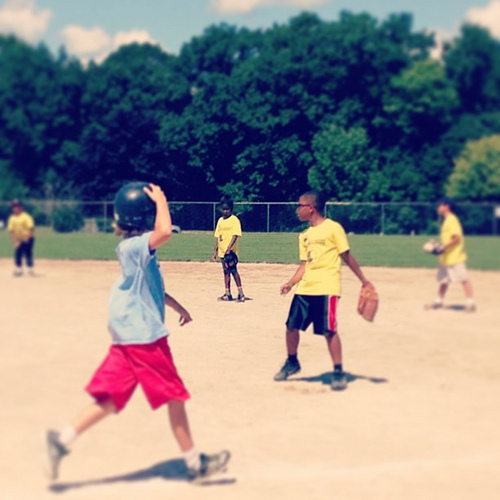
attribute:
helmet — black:
[114, 179, 156, 229]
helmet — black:
[108, 177, 168, 245]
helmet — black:
[107, 178, 167, 235]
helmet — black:
[109, 172, 172, 239]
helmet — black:
[113, 175, 167, 239]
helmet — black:
[113, 180, 170, 242]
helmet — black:
[109, 175, 178, 245]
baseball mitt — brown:
[352, 275, 386, 325]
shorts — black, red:
[287, 289, 343, 338]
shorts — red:
[85, 330, 199, 420]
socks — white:
[175, 443, 212, 479]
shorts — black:
[219, 246, 246, 278]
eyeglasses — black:
[294, 201, 312, 208]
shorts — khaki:
[435, 260, 468, 285]